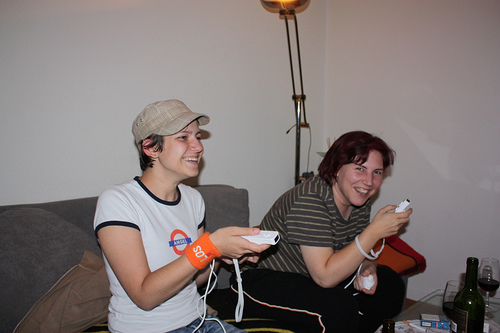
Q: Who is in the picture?
A: People.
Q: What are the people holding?
A: Game controllers.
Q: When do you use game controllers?
A: Play.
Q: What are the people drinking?
A: Wine.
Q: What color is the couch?
A: Grey.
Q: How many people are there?
A: Two.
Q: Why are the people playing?
A: For fun.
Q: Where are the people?
A: Living room.